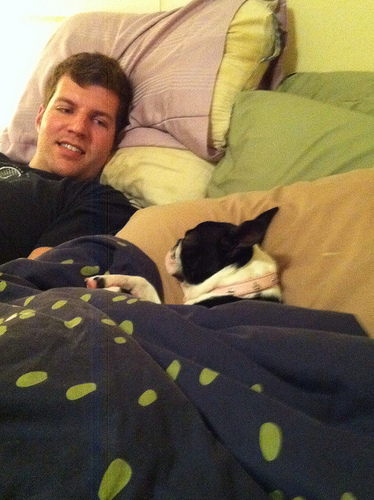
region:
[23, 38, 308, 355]
man in bed with dog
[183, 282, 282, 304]
pink collar on dog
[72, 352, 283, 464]
light green designs on blanket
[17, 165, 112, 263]
black short sleeved tee shirt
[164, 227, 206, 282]
white nose on black head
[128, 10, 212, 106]
purple case on pillow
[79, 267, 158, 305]
dog paw on top of blanket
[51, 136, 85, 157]
teeth in man's mouth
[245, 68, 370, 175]
two green pillows stacked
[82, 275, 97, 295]
pink pad on dog paw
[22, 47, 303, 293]
man looking over at dog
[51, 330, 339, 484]
green dots on black blanket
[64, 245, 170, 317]
paw over top of blanket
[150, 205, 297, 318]
dog's head resting on tan pillow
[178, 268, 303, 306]
dog wearing pink collar with studs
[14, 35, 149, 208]
man's head elevated on two pillows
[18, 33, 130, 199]
man smiling and showing teeth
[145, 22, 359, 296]
spare green pillows behind dog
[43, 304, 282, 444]
folds across the blankets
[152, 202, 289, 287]
black and white face with black ears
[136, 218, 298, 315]
black and white dog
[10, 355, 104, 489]
green spots on a blanket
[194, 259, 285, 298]
pink collar on the dog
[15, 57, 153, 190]
man looking at the dog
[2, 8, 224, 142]
pink pillow case covering pillow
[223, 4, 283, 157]
white pillow sticking out of the pillowcase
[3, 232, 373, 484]
blue blanket covering the dog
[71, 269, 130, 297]
dogs pink and black paws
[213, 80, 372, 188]
green pillowcase resting on bed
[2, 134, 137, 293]
black shirt being worn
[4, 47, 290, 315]
Man and dog laying in bed.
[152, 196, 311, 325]
Dog's black and white head on pillow.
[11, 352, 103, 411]
Green dots on blue bedspread.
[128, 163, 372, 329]
Tan colored pillow case.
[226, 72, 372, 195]
Two green pillow cases.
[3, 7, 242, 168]
A Lavender pillow case.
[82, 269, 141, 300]
Dog's paw on top of bedspread.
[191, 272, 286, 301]
Pink collar around dog's neck.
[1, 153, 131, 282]
Man dressed in black t-shirt.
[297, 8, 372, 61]
Yellow wall behind bed.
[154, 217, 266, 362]
Dog laying under covers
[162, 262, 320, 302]
Dog is black and white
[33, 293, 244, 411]
Blanket is blue with spots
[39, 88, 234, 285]
Man laying beside dog in bed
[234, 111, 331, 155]
Pillow is inside green pillowcase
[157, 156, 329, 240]
Dog's head is on brown pillowcase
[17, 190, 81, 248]
Man is wearing black shirt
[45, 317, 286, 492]
Green spots on blue blanket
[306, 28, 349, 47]
Wall is creme color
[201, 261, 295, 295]
Dog has on pink collar